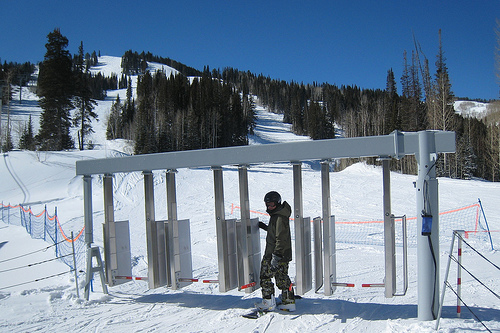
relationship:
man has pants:
[211, 190, 324, 315] [255, 260, 305, 302]